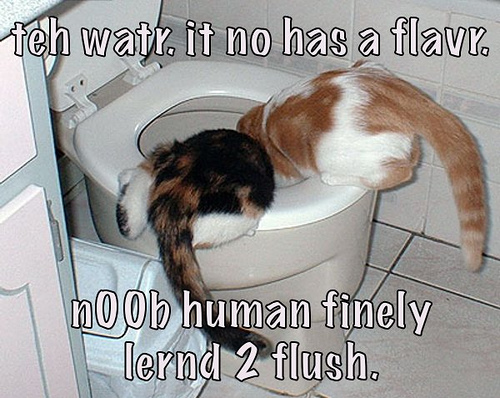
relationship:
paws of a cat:
[316, 163, 415, 190] [247, 61, 499, 267]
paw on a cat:
[115, 157, 150, 242] [110, 127, 271, 242]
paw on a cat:
[201, 208, 266, 246] [110, 127, 271, 242]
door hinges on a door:
[48, 217, 65, 262] [2, 182, 80, 395]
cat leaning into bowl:
[236, 61, 486, 276] [141, 69, 388, 244]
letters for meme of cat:
[11, 15, 490, 59] [101, 107, 301, 367]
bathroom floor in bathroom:
[194, 217, 499, 398] [0, 3, 489, 388]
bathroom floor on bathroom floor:
[194, 217, 499, 398] [194, 217, 499, 398]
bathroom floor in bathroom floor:
[194, 217, 499, 398] [189, 222, 499, 394]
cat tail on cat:
[155, 192, 272, 361] [82, 100, 302, 366]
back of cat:
[168, 127, 273, 222] [82, 100, 302, 366]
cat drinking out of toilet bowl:
[113, 129, 276, 357] [193, 186, 377, 388]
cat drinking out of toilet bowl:
[236, 61, 486, 276] [193, 186, 377, 388]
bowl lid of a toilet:
[41, 0, 168, 130] [66, 18, 377, 394]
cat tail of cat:
[382, 93, 489, 273] [236, 48, 488, 299]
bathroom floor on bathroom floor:
[194, 217, 499, 398] [189, 222, 499, 394]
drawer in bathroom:
[5, 39, 42, 178] [0, 3, 489, 388]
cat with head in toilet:
[236, 61, 486, 276] [44, 1, 376, 326]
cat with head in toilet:
[102, 120, 264, 301] [44, 1, 376, 326]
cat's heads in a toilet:
[78, 55, 498, 355] [44, 1, 376, 326]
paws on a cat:
[316, 163, 415, 190] [103, 122, 283, 352]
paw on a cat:
[115, 182, 149, 242] [103, 122, 283, 352]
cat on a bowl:
[232, 51, 499, 276] [76, 56, 379, 232]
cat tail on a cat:
[382, 93, 489, 273] [247, 61, 499, 267]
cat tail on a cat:
[155, 192, 272, 361] [103, 122, 283, 352]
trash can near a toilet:
[66, 229, 211, 396] [76, 55, 401, 389]